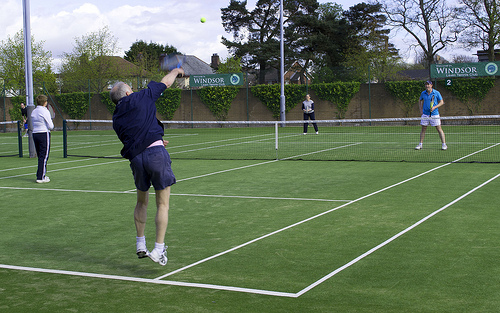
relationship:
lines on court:
[61, 169, 430, 309] [1, 98, 496, 303]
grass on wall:
[2, 76, 499, 125] [0, 76, 497, 123]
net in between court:
[2, 112, 497, 167] [0, 123, 499, 311]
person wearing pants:
[29, 95, 54, 183] [31, 129, 68, 197]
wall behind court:
[1, 72, 498, 121] [0, 123, 499, 311]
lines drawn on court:
[7, 126, 492, 304] [0, 126, 499, 310]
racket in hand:
[428, 98, 436, 115] [153, 54, 193, 94]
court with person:
[0, 126, 499, 310] [25, 92, 55, 184]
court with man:
[0, 126, 499, 310] [110, 67, 186, 266]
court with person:
[0, 126, 499, 310] [297, 94, 320, 136]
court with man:
[0, 126, 499, 310] [416, 82, 447, 151]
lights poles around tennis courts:
[257, 7, 303, 120] [34, 47, 461, 298]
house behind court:
[159, 53, 214, 88] [0, 126, 499, 310]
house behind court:
[96, 53, 151, 85] [0, 126, 499, 310]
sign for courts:
[189, 72, 247, 89] [22, 139, 477, 302]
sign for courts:
[189, 72, 247, 89] [14, 105, 487, 169]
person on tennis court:
[15, 97, 35, 144] [3, 100, 204, 148]